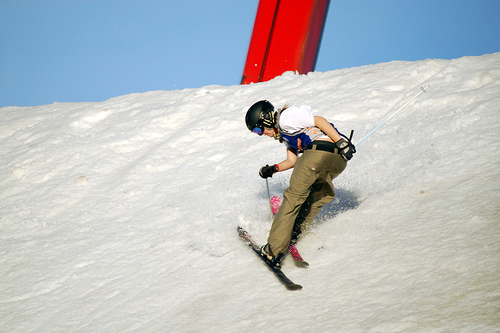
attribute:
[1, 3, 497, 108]
sky — blue, clear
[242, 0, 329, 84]
object — red, big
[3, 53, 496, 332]
snow — big, fat, white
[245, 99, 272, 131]
helmet — black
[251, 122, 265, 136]
surfing goggles — blue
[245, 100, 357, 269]
man — skiing, skating, snow skating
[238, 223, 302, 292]
ski — black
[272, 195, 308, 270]
ski — pink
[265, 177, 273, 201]
stick — white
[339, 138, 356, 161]
glove — black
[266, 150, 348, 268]
trouser — green, khaki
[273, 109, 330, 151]
shirt — blue, white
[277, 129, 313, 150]
vest — blue